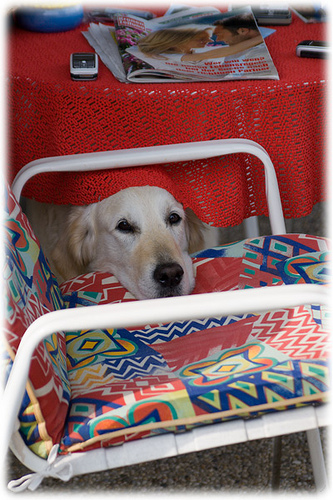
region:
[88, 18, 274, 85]
magazines sitting on the table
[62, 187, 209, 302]
the cute dog head resting on the colorful chair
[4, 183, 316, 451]
the colorful chair by the table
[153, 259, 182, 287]
the black nose of the dog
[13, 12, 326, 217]
the table next to the chair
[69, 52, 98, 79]
the cell phone sitting on the table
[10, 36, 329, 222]
the red tablecloth sitting on the table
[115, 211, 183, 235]
the big brown eyes of the cute dog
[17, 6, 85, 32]
a blue container on the table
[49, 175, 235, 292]
The dogs head is resting on the chair.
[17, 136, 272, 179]
The chair has a white arm.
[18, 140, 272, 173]
The chair arm is metal.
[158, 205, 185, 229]
The dogs eye is dark.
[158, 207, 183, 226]
The dogs eye is open.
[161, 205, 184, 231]
The dogs eye is brown.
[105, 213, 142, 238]
The dogs eye is dark.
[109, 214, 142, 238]
The dogs eye is brown.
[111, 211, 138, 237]
The dogs eye is open.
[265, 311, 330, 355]
The chair cushion has a chevron design.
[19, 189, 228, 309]
dog resting head on chair cushion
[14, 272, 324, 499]
white chair arm rest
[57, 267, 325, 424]
abstract pattern on seat cushion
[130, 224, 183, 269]
tan spot on white dog's nose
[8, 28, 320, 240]
red crochet table cloth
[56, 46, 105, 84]
cell phone on table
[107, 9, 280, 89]
magazine on table top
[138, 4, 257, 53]
man and woman on cover of magazine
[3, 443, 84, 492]
knot tied on edge of seat cushion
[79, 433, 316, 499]
ground underneath seat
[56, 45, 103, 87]
The cell phone is on the table.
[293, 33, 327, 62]
The cell phone is laying on the table.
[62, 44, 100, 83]
The cell phone is black.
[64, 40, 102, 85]
The cell phone has chrome trim.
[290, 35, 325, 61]
The cell phone is black.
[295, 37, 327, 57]
The cell phone has chrome trim.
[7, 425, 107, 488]
The chair cushion is tied to the chair.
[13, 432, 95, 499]
The cushion tie is white.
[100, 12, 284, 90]
The magazines are on the table.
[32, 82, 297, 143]
The tablecloth is red.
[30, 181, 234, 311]
dog under a table cloth on chair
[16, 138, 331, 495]
lawn chair with dog head on seat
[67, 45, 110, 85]
white and black cell phone on table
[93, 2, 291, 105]
magazines on table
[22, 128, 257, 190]
white metal arm of chair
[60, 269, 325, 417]
lawn seat with designs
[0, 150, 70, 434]
back cushion on lawn chair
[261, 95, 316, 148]
red table cloth on table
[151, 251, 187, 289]
black nose of dog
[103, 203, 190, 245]
two eyes of dog